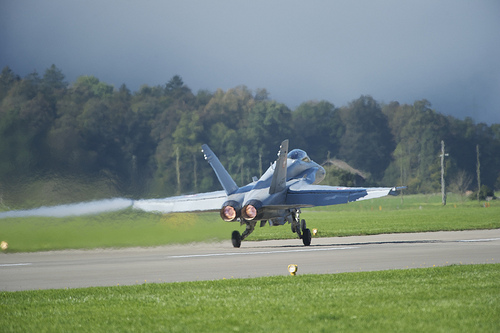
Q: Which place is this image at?
A: It is at the forest.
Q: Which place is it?
A: It is a forest.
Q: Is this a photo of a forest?
A: Yes, it is showing a forest.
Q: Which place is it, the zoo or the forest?
A: It is the forest.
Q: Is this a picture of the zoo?
A: No, the picture is showing the forest.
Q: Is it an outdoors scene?
A: Yes, it is outdoors.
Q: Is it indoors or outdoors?
A: It is outdoors.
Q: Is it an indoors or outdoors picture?
A: It is outdoors.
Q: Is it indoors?
A: No, it is outdoors.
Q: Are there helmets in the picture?
A: No, there are no helmets.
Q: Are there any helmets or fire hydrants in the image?
A: No, there are no helmets or fire hydrants.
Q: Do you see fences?
A: No, there are no fences.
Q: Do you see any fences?
A: No, there are no fences.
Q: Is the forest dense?
A: Yes, the forest is dense.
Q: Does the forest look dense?
A: Yes, the forest is dense.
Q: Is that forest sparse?
A: No, the forest is dense.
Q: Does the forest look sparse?
A: No, the forest is dense.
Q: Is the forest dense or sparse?
A: The forest is dense.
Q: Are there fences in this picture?
A: No, there are no fences.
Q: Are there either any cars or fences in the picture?
A: No, there are no fences or cars.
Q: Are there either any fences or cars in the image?
A: No, there are no fences or cars.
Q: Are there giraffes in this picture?
A: No, there are no giraffes.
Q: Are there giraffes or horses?
A: No, there are no giraffes or horses.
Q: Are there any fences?
A: No, there are no fences.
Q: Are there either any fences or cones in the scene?
A: No, there are no fences or cones.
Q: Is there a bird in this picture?
A: No, there are no birds.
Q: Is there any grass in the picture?
A: Yes, there is grass.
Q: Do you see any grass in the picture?
A: Yes, there is grass.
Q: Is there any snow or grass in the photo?
A: Yes, there is grass.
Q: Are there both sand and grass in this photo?
A: No, there is grass but no sand.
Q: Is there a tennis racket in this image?
A: No, there are no rackets.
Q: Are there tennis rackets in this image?
A: No, there are no tennis rackets.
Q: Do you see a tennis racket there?
A: No, there are no rackets.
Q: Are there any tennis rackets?
A: No, there are no tennis rackets.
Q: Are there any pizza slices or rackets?
A: No, there are no rackets or pizza slices.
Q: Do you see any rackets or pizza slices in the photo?
A: No, there are no rackets or pizza slices.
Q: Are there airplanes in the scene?
A: Yes, there is an airplane.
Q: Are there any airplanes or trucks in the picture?
A: Yes, there is an airplane.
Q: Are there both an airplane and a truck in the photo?
A: No, there is an airplane but no trucks.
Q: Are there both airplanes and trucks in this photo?
A: No, there is an airplane but no trucks.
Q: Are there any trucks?
A: No, there are no trucks.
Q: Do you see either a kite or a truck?
A: No, there are no trucks or kites.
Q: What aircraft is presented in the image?
A: The aircraft is an airplane.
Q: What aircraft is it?
A: The aircraft is an airplane.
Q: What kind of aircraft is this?
A: This is an airplane.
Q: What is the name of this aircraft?
A: This is an airplane.